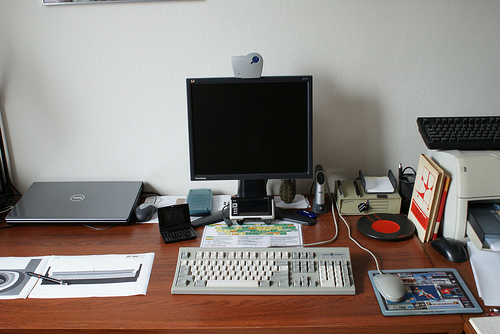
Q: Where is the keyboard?
A: Desk.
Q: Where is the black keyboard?
A: On top of the white printer.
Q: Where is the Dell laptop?
A: Left of the flat screen monitor.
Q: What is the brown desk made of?
A: Wood.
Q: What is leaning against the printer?
A: Orange and white books.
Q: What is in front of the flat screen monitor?
A: White paper with yellow, green, and black.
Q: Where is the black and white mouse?
A: Next to the Dell laptop.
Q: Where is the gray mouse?
A: On top of the mouse pad.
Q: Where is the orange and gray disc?
A: Next to the books.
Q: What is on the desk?
A: The black computer monitor.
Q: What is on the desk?
A: The grey computer keyboard.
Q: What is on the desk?
A: The grey mouse and mousepad.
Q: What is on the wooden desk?
A: The laptop.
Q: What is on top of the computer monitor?
A: The web camera.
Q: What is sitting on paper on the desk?
A: The black pen.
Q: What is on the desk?
A: The computer printer.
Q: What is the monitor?
A: For the desktop computer.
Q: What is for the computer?
A: The grey keyboard.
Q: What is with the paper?
A: The white printer.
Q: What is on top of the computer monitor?
A: Webcam.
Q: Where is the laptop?
A: To the left of the computer monitor.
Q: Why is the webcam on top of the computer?
A: Because the monitor doesn't have an embedded cam.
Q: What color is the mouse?
A: Gray.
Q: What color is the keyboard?
A: Gray and white.